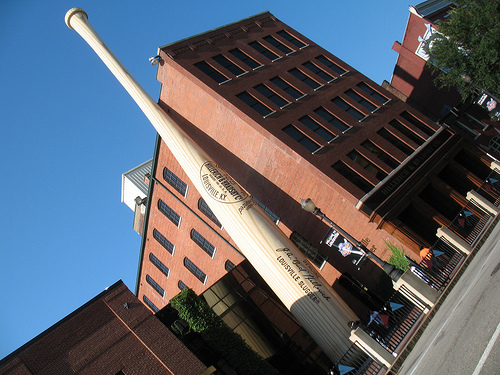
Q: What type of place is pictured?
A: It is a museum.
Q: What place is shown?
A: It is a museum.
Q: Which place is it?
A: It is a museum.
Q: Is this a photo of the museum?
A: Yes, it is showing the museum.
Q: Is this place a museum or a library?
A: It is a museum.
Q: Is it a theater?
A: No, it is a museum.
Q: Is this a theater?
A: No, it is a museum.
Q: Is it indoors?
A: Yes, it is indoors.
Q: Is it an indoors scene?
A: Yes, it is indoors.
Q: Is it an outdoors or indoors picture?
A: It is indoors.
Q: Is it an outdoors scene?
A: No, it is indoors.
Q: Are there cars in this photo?
A: No, there are no cars.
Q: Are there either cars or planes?
A: No, there are no cars or planes.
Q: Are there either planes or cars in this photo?
A: No, there are no cars or planes.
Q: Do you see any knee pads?
A: No, there are no knee pads.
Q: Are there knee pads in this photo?
A: No, there are no knee pads.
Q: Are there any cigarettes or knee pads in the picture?
A: No, there are no knee pads or cigarettes.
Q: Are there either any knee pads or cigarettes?
A: No, there are no knee pads or cigarettes.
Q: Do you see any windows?
A: Yes, there are windows.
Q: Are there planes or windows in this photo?
A: Yes, there are windows.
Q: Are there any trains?
A: No, there are no trains.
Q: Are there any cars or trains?
A: No, there are no trains or cars.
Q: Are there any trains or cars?
A: No, there are no trains or cars.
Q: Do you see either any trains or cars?
A: No, there are no trains or cars.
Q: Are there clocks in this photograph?
A: No, there are no clocks.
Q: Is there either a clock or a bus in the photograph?
A: No, there are no clocks or buses.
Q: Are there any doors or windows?
A: Yes, there are windows.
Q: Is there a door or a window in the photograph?
A: Yes, there are windows.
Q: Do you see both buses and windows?
A: No, there are windows but no buses.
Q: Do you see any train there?
A: No, there are no trains.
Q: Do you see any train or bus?
A: No, there are no trains or buses.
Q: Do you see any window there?
A: Yes, there is a window.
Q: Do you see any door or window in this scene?
A: Yes, there is a window.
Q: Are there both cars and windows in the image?
A: No, there is a window but no cars.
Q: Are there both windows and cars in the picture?
A: No, there is a window but no cars.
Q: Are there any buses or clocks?
A: No, there are no clocks or buses.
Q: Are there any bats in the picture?
A: Yes, there is a bat.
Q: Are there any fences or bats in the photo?
A: Yes, there is a bat.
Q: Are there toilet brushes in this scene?
A: No, there are no toilet brushes.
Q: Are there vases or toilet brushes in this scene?
A: No, there are no toilet brushes or vases.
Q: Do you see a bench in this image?
A: No, there are no benches.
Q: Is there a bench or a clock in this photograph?
A: No, there are no benches or clocks.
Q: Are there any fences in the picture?
A: Yes, there is a fence.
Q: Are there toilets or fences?
A: Yes, there is a fence.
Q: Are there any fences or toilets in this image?
A: Yes, there is a fence.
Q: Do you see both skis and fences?
A: No, there is a fence but no skis.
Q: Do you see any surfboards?
A: No, there are no surfboards.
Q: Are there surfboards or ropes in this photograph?
A: No, there are no surfboards or ropes.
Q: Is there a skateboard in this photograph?
A: No, there are no skateboards.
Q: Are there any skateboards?
A: No, there are no skateboards.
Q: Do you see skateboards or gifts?
A: No, there are no skateboards or gifts.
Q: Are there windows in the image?
A: Yes, there is a window.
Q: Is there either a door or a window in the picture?
A: Yes, there is a window.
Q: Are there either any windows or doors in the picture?
A: Yes, there is a window.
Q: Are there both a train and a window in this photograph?
A: No, there is a window but no trains.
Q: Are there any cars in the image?
A: No, there are no cars.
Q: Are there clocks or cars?
A: No, there are no cars or clocks.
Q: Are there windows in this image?
A: Yes, there is a window.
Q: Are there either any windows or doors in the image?
A: Yes, there is a window.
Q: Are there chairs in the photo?
A: No, there are no chairs.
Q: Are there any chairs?
A: No, there are no chairs.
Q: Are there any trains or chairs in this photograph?
A: No, there are no chairs or trains.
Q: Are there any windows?
A: Yes, there is a window.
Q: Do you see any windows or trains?
A: Yes, there is a window.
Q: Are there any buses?
A: No, there are no buses.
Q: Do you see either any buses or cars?
A: No, there are no buses or cars.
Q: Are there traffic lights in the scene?
A: No, there are no traffic lights.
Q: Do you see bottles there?
A: No, there are no bottles.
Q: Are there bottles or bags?
A: No, there are no bottles or bags.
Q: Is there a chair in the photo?
A: No, there are no chairs.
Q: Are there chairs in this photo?
A: No, there are no chairs.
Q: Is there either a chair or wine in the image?
A: No, there are no chairs or wine.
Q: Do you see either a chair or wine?
A: No, there are no chairs or wine.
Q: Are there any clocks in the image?
A: No, there are no clocks.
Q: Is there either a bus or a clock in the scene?
A: No, there are no clocks or buses.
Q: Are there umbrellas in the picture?
A: No, there are no umbrellas.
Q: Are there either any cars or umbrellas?
A: No, there are no umbrellas or cars.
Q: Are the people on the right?
A: Yes, the people are on the right of the image.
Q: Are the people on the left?
A: No, the people are on the right of the image.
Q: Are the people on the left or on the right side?
A: The people are on the right of the image.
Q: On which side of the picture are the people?
A: The people are on the right of the image.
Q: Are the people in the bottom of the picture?
A: Yes, the people are in the bottom of the image.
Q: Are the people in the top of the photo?
A: No, the people are in the bottom of the image.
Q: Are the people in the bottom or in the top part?
A: The people are in the bottom of the image.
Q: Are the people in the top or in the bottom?
A: The people are in the bottom of the image.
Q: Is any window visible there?
A: Yes, there are windows.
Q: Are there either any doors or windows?
A: Yes, there are windows.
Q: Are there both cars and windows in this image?
A: No, there are windows but no cars.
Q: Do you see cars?
A: No, there are no cars.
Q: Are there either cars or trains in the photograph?
A: No, there are no cars or trains.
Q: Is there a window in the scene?
A: Yes, there is a window.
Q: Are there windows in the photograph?
A: Yes, there is a window.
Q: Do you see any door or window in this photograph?
A: Yes, there is a window.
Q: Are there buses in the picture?
A: No, there are no buses.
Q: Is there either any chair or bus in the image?
A: No, there are no buses or chairs.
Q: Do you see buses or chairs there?
A: No, there are no buses or chairs.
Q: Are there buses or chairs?
A: No, there are no buses or chairs.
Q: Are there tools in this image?
A: No, there are no tools.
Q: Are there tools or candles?
A: No, there are no tools or candles.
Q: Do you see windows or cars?
A: Yes, there is a window.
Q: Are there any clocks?
A: No, there are no clocks.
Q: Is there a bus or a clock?
A: No, there are no clocks or buses.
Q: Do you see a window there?
A: Yes, there is a window.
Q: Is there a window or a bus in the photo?
A: Yes, there is a window.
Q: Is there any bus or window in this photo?
A: Yes, there is a window.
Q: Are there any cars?
A: No, there are no cars.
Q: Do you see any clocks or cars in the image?
A: No, there are no cars or clocks.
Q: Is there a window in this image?
A: Yes, there is a window.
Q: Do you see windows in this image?
A: Yes, there is a window.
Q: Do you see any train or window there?
A: Yes, there is a window.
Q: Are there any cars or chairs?
A: No, there are no chairs or cars.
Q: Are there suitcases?
A: No, there are no suitcases.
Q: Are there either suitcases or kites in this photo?
A: No, there are no suitcases or kites.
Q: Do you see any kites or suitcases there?
A: No, there are no suitcases or kites.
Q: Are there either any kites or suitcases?
A: No, there are no suitcases or kites.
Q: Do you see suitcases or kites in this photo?
A: No, there are no suitcases or kites.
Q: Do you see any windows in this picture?
A: Yes, there are windows.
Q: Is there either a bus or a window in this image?
A: Yes, there are windows.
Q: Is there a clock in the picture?
A: No, there are no clocks.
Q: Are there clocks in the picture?
A: No, there are no clocks.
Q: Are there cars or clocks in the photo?
A: No, there are no clocks or cars.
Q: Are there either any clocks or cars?
A: No, there are no clocks or cars.